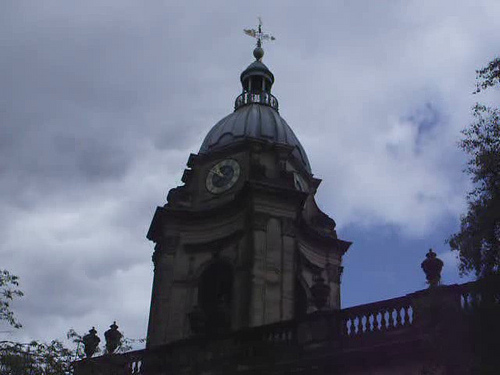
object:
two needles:
[209, 163, 223, 178]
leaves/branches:
[0, 264, 72, 375]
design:
[185, 257, 237, 332]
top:
[195, 11, 313, 164]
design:
[294, 247, 334, 315]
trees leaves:
[0, 267, 86, 375]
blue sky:
[344, 228, 423, 296]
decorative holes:
[250, 300, 417, 356]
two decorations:
[80, 320, 126, 357]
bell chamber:
[189, 251, 232, 336]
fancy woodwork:
[146, 178, 350, 246]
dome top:
[208, 19, 320, 117]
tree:
[0, 263, 95, 373]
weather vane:
[238, 14, 278, 64]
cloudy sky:
[2, 5, 500, 354]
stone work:
[256, 230, 294, 328]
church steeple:
[234, 15, 280, 105]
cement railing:
[74, 280, 500, 375]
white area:
[205, 160, 239, 194]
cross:
[243, 17, 275, 54]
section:
[151, 205, 252, 345]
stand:
[232, 88, 284, 108]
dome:
[190, 17, 310, 163]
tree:
[443, 41, 499, 282]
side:
[452, 10, 499, 348]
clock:
[204, 157, 241, 195]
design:
[252, 178, 309, 325]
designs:
[201, 102, 303, 149]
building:
[145, 10, 359, 375]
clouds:
[0, 0, 500, 375]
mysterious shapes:
[30, 61, 131, 201]